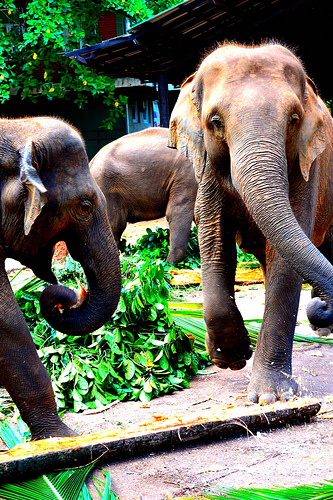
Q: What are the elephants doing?
A: Walking.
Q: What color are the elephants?
A: Grey.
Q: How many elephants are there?
A: 3.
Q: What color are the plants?
A: Green.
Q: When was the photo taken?
A: Daytime.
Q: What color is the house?
A: Blue.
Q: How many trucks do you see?
A: 2.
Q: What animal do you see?
A: Elephant.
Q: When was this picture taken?
A: During daylight.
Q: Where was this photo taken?
A: A zoo.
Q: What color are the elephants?
A: Gray.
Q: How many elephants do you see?
A: 3.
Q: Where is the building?
A: Behind the elephants.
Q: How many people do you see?
A: 0.